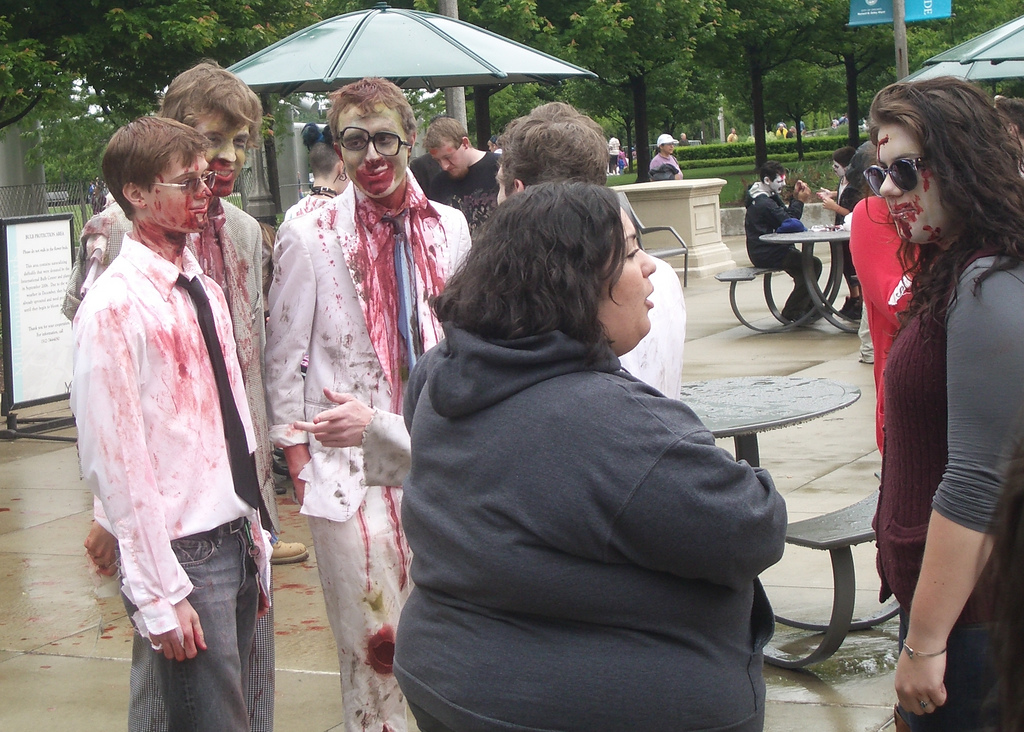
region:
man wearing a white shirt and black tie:
[82, 246, 273, 589]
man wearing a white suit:
[284, 183, 499, 654]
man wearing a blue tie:
[384, 214, 423, 383]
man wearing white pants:
[307, 480, 410, 722]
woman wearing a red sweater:
[836, 260, 1001, 589]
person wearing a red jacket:
[846, 189, 908, 468]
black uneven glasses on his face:
[319, 120, 414, 169]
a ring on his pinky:
[147, 636, 176, 662]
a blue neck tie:
[379, 212, 431, 383]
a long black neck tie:
[174, 260, 289, 513]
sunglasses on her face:
[856, 135, 943, 192]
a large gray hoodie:
[343, 335, 818, 729]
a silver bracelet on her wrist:
[893, 623, 983, 678]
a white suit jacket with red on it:
[265, 184, 463, 524]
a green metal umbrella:
[201, 3, 598, 103]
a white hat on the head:
[656, 124, 686, 151]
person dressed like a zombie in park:
[70, 109, 286, 723]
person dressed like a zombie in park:
[153, 55, 277, 581]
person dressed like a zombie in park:
[266, 78, 429, 727]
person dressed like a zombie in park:
[873, 77, 1017, 727]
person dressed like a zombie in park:
[738, 159, 811, 322]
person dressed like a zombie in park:
[808, 137, 854, 296]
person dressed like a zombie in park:
[403, 179, 767, 718]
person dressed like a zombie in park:
[412, 110, 515, 243]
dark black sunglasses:
[864, 161, 923, 194]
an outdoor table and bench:
[672, 367, 892, 666]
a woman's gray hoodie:
[397, 361, 793, 728]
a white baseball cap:
[653, 133, 680, 147]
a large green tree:
[699, 3, 820, 177]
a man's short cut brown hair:
[422, 116, 471, 155]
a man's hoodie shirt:
[737, 179, 802, 268]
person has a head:
[98, 117, 217, 236]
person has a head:
[156, 63, 256, 193]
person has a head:
[330, 81, 410, 200]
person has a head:
[499, 103, 602, 195]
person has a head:
[423, 186, 652, 363]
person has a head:
[866, 77, 1015, 249]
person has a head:
[657, 129, 678, 153]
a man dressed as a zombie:
[92, 114, 282, 728]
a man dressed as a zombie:
[77, 62, 278, 572]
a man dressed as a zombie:
[261, 71, 467, 721]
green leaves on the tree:
[631, 80, 695, 126]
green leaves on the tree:
[699, 69, 742, 107]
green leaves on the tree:
[605, 51, 660, 86]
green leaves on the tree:
[175, 1, 224, 47]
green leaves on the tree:
[87, 7, 177, 106]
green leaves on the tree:
[43, 51, 127, 138]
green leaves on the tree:
[716, 54, 835, 62]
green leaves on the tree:
[646, 51, 707, 100]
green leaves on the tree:
[547, 66, 602, 104]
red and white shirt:
[299, 183, 503, 560]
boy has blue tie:
[328, 204, 443, 458]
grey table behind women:
[679, 398, 915, 659]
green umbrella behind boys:
[211, 15, 490, 82]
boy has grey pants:
[132, 528, 253, 725]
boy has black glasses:
[346, 113, 448, 216]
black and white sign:
[5, 208, 105, 488]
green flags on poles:
[872, 2, 955, 42]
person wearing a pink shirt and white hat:
[642, 126, 681, 188]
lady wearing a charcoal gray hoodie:
[383, 177, 804, 729]